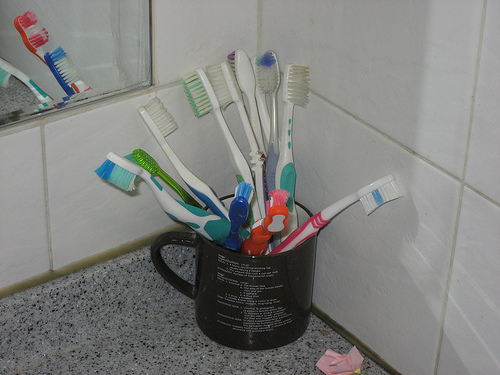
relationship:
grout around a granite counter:
[4, 222, 199, 293] [1, 227, 385, 375]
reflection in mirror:
[0, 10, 93, 110] [1, 0, 167, 136]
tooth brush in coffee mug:
[93, 152, 251, 247] [150, 193, 318, 351]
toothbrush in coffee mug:
[137, 97, 232, 219] [150, 193, 318, 351]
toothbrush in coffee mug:
[180, 67, 261, 228] [150, 193, 318, 351]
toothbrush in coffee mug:
[207, 59, 269, 218] [150, 193, 318, 351]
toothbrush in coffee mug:
[226, 49, 269, 217] [150, 193, 318, 351]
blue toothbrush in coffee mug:
[221, 181, 254, 253] [150, 193, 318, 351]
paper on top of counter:
[313, 340, 368, 375] [1, 240, 396, 375]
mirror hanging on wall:
[1, 0, 167, 136] [0, 1, 260, 297]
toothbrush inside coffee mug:
[271, 169, 406, 256] [150, 193, 318, 351]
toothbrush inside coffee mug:
[268, 64, 306, 252] [150, 193, 318, 351]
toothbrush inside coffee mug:
[251, 45, 282, 232] [150, 193, 318, 351]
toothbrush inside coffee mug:
[178, 69, 260, 249] [150, 193, 318, 351]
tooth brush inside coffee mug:
[93, 152, 251, 247] [150, 193, 318, 351]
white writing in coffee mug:
[209, 254, 294, 333] [150, 193, 318, 351]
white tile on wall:
[378, 60, 471, 155] [263, 1, 499, 371]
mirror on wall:
[1, 0, 167, 136] [0, 1, 260, 297]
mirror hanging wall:
[1, 0, 167, 136] [4, 6, 482, 357]